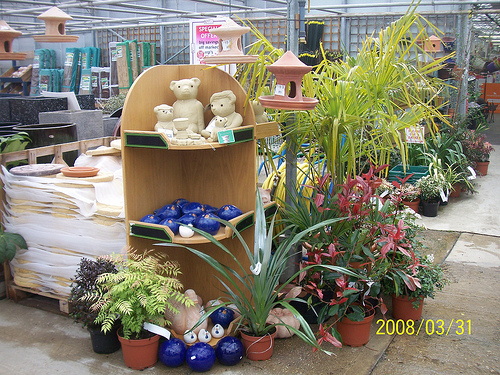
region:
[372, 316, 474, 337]
Date stamp on photograph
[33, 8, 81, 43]
Bird feeder on display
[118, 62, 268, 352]
Wooden product display shelf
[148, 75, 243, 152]
Decorative ceramic bears for sale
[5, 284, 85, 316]
Wooden pallet supporting pottery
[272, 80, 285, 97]
Price tag on bird feeder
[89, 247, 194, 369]
Potted plant on floor for sale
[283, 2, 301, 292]
Metal structure support pole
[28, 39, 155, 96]
Garden ground materials on display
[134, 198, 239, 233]
Blue decorative pottery for sale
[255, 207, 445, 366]
plants on the floor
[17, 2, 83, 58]
bird house hanging from the ceiling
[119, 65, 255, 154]
bears made of pottery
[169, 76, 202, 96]
the eyes are black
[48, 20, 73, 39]
a hole in the birdhouse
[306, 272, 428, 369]
the flower pots are amber colored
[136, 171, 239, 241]
blue mushroom shaped pottery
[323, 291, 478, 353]
the date on the right bottom of the picture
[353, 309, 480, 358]
the numbers are yellow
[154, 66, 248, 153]
stone white sculpture bear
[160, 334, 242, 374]
blue glass ball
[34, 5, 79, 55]
bird house display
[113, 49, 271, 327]
brown stand with decorative stuff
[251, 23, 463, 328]
various plants in the floor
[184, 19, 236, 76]
signs posted in the wall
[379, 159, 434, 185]
green bucket in the floor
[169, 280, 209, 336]
swan sculpture in the bottom shelve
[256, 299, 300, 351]
pumpkin sculpture in the floor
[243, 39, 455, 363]
several healthy plants in planters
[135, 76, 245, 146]
several brown stone teddy bears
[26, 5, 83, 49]
a brown wooden birdhouse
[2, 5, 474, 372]
a room filled with landscaping products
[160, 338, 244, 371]
three blue balls on the ground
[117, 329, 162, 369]
a small brown planter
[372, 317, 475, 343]
the date stamp in the photo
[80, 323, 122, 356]
a small green planter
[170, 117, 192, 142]
a small white stone cup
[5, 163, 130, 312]
sheets of plastic seperating several products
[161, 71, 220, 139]
teddy bears are on the shelf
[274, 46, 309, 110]
a clay bird house is hanging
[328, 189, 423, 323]
plant are on display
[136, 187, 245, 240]
garden decorations are on display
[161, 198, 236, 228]
blue garden decorations for sale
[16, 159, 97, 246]
garden stepping stones are stacked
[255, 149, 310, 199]
a yellow hose is coiled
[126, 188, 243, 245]
group of blue items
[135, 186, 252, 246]
group of blue items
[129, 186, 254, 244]
group of blue items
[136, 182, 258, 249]
group of blue items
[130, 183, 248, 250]
group of blue items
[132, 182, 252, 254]
group of blue items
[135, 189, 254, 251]
group of blue items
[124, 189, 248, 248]
group of blue items